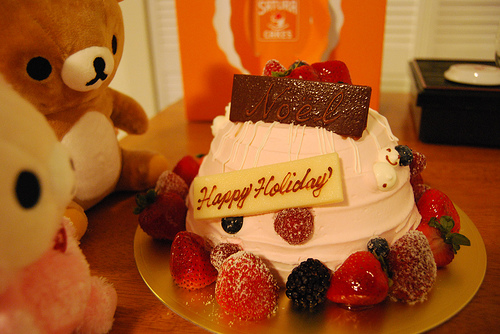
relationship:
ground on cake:
[383, 120, 455, 171] [142, 40, 476, 330]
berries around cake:
[327, 251, 380, 305] [184, 109, 426, 250]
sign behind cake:
[161, 0, 401, 141] [152, 60, 472, 280]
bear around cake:
[2, 0, 173, 243] [188, 50, 453, 313]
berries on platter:
[327, 251, 388, 305] [133, 198, 487, 332]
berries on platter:
[284, 258, 332, 309] [133, 198, 487, 332]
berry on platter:
[213, 247, 283, 324] [133, 198, 487, 332]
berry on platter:
[170, 229, 216, 289] [133, 198, 487, 332]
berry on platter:
[137, 189, 187, 242] [133, 198, 487, 332]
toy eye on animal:
[10, 164, 49, 209] [3, 76, 118, 329]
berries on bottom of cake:
[284, 258, 332, 309] [183, 63, 434, 283]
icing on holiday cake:
[372, 146, 397, 195] [127, 57, 454, 326]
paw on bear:
[112, 95, 152, 134] [2, 3, 172, 243]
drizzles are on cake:
[312, 126, 335, 148] [126, 54, 472, 326]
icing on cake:
[190, 106, 417, 272] [126, 54, 472, 326]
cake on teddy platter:
[130, 58, 472, 321] [140, 165, 490, 332]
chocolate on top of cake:
[229, 75, 366, 135] [183, 63, 434, 283]